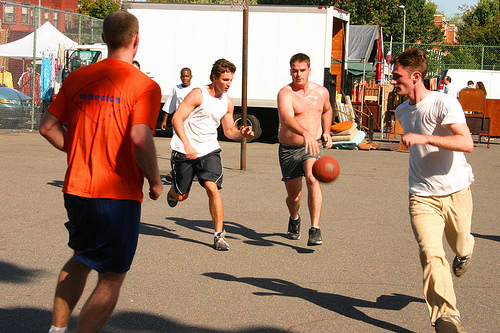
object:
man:
[163, 55, 254, 254]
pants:
[404, 182, 479, 332]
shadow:
[201, 271, 437, 333]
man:
[33, 8, 171, 333]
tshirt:
[386, 95, 478, 200]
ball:
[310, 155, 343, 183]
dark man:
[161, 66, 203, 182]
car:
[0, 80, 39, 130]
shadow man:
[158, 212, 325, 257]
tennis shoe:
[208, 227, 232, 252]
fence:
[0, 0, 106, 132]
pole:
[235, 0, 252, 171]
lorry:
[51, 0, 358, 147]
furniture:
[457, 86, 500, 148]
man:
[382, 40, 487, 332]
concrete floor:
[0, 127, 500, 333]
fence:
[384, 40, 500, 76]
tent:
[0, 18, 87, 61]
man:
[275, 52, 336, 251]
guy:
[379, 43, 488, 333]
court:
[1, 130, 500, 333]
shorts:
[276, 137, 324, 182]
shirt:
[160, 84, 202, 116]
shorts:
[168, 148, 225, 204]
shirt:
[45, 57, 158, 201]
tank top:
[172, 85, 225, 158]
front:
[0, 84, 37, 120]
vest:
[166, 84, 227, 158]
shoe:
[305, 225, 324, 247]